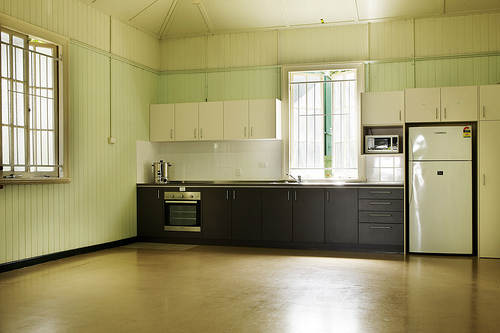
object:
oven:
[145, 181, 205, 242]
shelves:
[139, 179, 407, 253]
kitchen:
[5, 6, 484, 320]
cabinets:
[149, 98, 281, 141]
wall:
[71, 25, 268, 94]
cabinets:
[359, 82, 500, 125]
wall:
[369, 27, 498, 87]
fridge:
[406, 122, 475, 254]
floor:
[31, 259, 498, 328]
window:
[282, 63, 367, 180]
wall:
[212, 26, 411, 58]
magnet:
[462, 126, 471, 139]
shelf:
[361, 148, 405, 167]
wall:
[146, 37, 284, 112]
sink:
[265, 177, 332, 186]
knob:
[170, 195, 174, 198]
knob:
[180, 195, 183, 198]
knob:
[190, 194, 193, 198]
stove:
[160, 186, 202, 235]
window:
[0, 18, 66, 182]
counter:
[137, 178, 205, 190]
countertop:
[139, 180, 403, 190]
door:
[410, 127, 473, 254]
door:
[158, 186, 202, 243]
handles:
[283, 152, 328, 244]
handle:
[408, 168, 415, 249]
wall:
[3, 190, 116, 255]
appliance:
[151, 159, 172, 184]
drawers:
[354, 190, 406, 246]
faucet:
[286, 173, 302, 183]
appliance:
[361, 134, 401, 153]